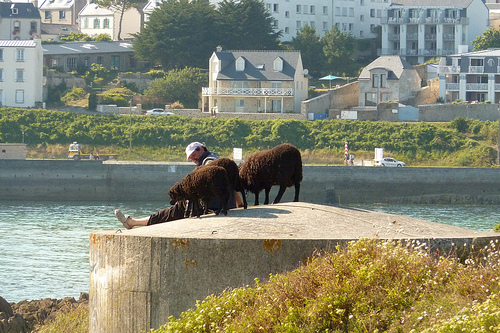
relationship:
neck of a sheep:
[173, 181, 186, 196] [169, 160, 235, 217]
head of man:
[184, 142, 206, 165] [114, 141, 239, 230]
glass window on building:
[370, 70, 383, 95] [341, 55, 421, 120]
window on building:
[383, 72, 396, 97] [350, 57, 416, 111]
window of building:
[360, 90, 378, 106] [346, 54, 421, 104]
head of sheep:
[159, 179, 186, 205] [158, 158, 239, 213]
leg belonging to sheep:
[183, 196, 193, 221] [165, 163, 233, 218]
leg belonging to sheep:
[192, 195, 197, 219] [165, 163, 233, 218]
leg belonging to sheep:
[250, 186, 260, 206] [234, 141, 304, 204]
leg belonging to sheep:
[260, 183, 271, 205] [234, 141, 304, 204]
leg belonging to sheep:
[213, 200, 221, 216] [165, 163, 233, 218]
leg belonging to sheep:
[220, 184, 230, 215] [165, 163, 233, 218]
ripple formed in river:
[48, 246, 90, 255] [1, 198, 484, 301]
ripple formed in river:
[47, 266, 90, 273] [1, 198, 484, 301]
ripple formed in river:
[2, 280, 22, 286] [1, 198, 484, 301]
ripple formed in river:
[3, 249, 37, 258] [1, 198, 484, 301]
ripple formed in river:
[2, 208, 46, 214] [1, 198, 484, 301]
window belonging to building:
[379, 92, 394, 102] [355, 54, 406, 109]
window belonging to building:
[267, 79, 287, 94] [202, 45, 286, 107]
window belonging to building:
[237, 82, 242, 89] [200, 44, 312, 119]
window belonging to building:
[235, 59, 244, 71] [200, 44, 312, 119]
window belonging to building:
[295, 2, 302, 16] [261, 1, 401, 52]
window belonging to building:
[100, 16, 107, 29] [34, 1, 85, 34]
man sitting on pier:
[114, 141, 239, 230] [85, 196, 485, 329]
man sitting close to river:
[114, 141, 239, 230] [5, 194, 496, 296]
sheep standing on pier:
[236, 139, 310, 207] [85, 196, 485, 329]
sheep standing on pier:
[165, 160, 235, 220] [85, 196, 485, 329]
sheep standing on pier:
[193, 156, 250, 208] [85, 196, 485, 329]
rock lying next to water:
[77, 290, 89, 300] [2, 192, 108, 284]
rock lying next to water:
[57, 295, 77, 305] [2, 192, 108, 284]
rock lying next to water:
[15, 300, 27, 313] [2, 192, 108, 284]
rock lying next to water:
[5, 309, 27, 330] [2, 192, 108, 284]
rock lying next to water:
[0, 294, 13, 315] [2, 192, 108, 284]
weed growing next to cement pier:
[417, 294, 485, 329] [85, 197, 497, 331]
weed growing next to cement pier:
[346, 297, 378, 329] [85, 197, 497, 331]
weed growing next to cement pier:
[352, 259, 383, 293] [85, 197, 497, 331]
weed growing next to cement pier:
[168, 310, 180, 330] [85, 197, 497, 331]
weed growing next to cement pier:
[251, 273, 260, 289] [85, 197, 497, 331]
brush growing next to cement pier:
[453, 265, 484, 305] [85, 197, 497, 331]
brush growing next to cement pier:
[366, 256, 416, 306] [85, 197, 497, 331]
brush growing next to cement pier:
[256, 270, 332, 307] [85, 197, 497, 331]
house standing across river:
[181, 25, 325, 131] [12, 207, 61, 274]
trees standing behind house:
[212, 0, 282, 46] [201, 44, 309, 119]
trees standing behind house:
[131, 0, 226, 68] [201, 44, 309, 119]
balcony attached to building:
[383, 10, 400, 25] [362, 7, 494, 105]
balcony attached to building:
[405, 9, 420, 24] [362, 7, 494, 105]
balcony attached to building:
[420, 5, 443, 24] [362, 7, 494, 105]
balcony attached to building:
[440, 7, 458, 26] [362, 7, 494, 105]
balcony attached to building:
[423, 26, 437, 40] [362, 7, 494, 105]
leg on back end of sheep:
[250, 186, 260, 206] [166, 144, 301, 212]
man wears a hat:
[114, 141, 239, 230] [185, 142, 205, 159]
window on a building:
[293, 3, 301, 13] [261, 0, 492, 66]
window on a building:
[305, 3, 315, 16] [261, 0, 492, 66]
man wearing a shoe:
[99, 124, 256, 218] [108, 208, 145, 233]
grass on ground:
[40, 236, 499, 332] [3, 247, 496, 333]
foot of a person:
[110, 206, 148, 224] [119, 141, 246, 230]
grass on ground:
[38, 245, 487, 332] [3, 247, 496, 333]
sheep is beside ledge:
[165, 164, 234, 220] [90, 193, 485, 331]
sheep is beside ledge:
[236, 141, 303, 207] [90, 193, 485, 331]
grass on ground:
[40, 236, 499, 332] [1, 233, 498, 331]